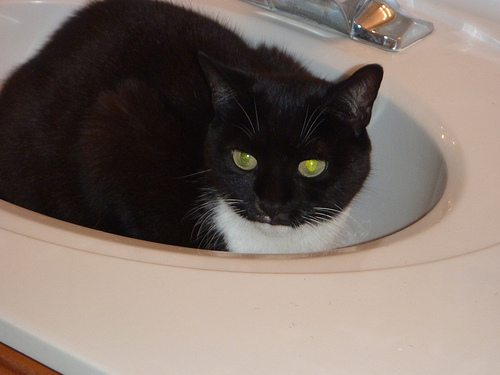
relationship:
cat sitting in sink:
[0, 3, 384, 252] [0, 1, 499, 294]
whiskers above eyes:
[230, 93, 263, 139] [229, 146, 328, 177]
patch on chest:
[214, 198, 351, 257] [178, 183, 358, 255]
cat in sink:
[0, 3, 384, 252] [0, 1, 499, 294]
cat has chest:
[0, 3, 384, 252] [178, 183, 358, 255]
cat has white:
[0, 3, 384, 252] [217, 200, 350, 254]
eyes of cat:
[229, 146, 328, 177] [0, 3, 384, 252]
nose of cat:
[256, 197, 290, 216] [0, 3, 384, 252]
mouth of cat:
[245, 211, 306, 236] [0, 3, 384, 252]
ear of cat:
[326, 63, 385, 122] [0, 3, 384, 252]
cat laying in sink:
[0, 3, 384, 252] [0, 1, 499, 294]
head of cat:
[198, 61, 379, 235] [0, 3, 384, 252]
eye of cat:
[298, 159, 328, 177] [0, 3, 384, 252]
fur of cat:
[3, 1, 273, 246] [0, 3, 384, 252]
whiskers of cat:
[187, 189, 248, 251] [0, 3, 384, 252]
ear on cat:
[326, 63, 385, 128] [0, 3, 384, 252]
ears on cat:
[195, 49, 252, 115] [0, 3, 384, 252]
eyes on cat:
[232, 149, 259, 171] [0, 3, 384, 252]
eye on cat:
[298, 159, 328, 177] [0, 3, 384, 252]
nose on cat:
[256, 197, 290, 216] [0, 3, 384, 252]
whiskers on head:
[187, 189, 248, 251] [198, 61, 379, 235]